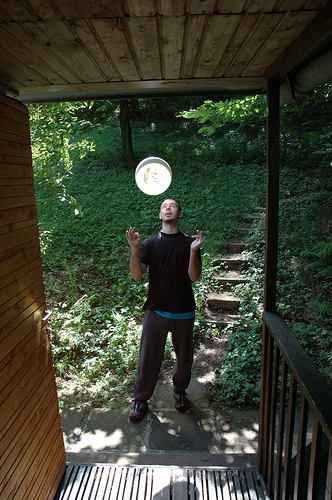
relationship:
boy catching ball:
[126, 199, 205, 422] [125, 145, 183, 195]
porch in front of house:
[42, 285, 325, 496] [2, 2, 325, 497]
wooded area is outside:
[27, 99, 332, 407] [32, 107, 263, 340]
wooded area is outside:
[1, 96, 56, 495] [32, 107, 263, 340]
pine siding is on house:
[1, 116, 30, 325] [0, 37, 290, 498]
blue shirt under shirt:
[154, 303, 199, 321] [139, 231, 203, 314]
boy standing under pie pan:
[126, 199, 205, 422] [133, 155, 175, 196]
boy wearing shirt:
[126, 199, 205, 422] [137, 230, 202, 313]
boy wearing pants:
[126, 199, 205, 422] [135, 297, 241, 441]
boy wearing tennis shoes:
[124, 197, 204, 427] [124, 390, 194, 423]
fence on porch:
[243, 301, 330, 499] [57, 459, 271, 499]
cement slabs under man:
[64, 407, 267, 451] [122, 196, 199, 426]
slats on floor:
[55, 464, 269, 500] [53, 459, 271, 499]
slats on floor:
[82, 465, 98, 499] [53, 459, 271, 499]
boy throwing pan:
[126, 199, 205, 422] [133, 152, 175, 199]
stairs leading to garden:
[189, 178, 283, 372] [42, 164, 127, 267]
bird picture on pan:
[144, 168, 150, 184] [134, 156, 172, 194]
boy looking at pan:
[126, 199, 205, 422] [131, 154, 173, 198]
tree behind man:
[116, 99, 142, 170] [122, 196, 199, 426]